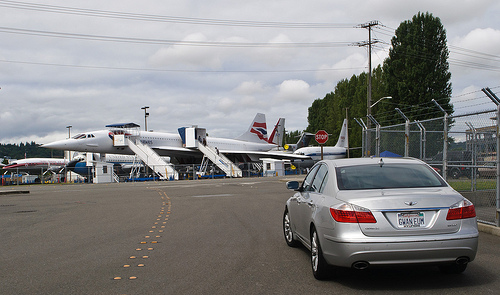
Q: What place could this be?
A: It is an airport.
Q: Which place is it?
A: It is an airport.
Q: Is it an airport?
A: Yes, it is an airport.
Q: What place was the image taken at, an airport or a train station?
A: It was taken at an airport.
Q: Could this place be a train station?
A: No, it is an airport.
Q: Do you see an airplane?
A: Yes, there is an airplane.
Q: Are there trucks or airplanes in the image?
A: Yes, there is an airplane.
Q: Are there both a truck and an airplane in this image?
A: No, there is an airplane but no trucks.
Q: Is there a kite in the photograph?
A: No, there are no kites.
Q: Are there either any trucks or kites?
A: No, there are no kites or trucks.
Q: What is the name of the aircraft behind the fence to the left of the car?
A: The aircraft is an airplane.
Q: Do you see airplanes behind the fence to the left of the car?
A: Yes, there is an airplane behind the fence.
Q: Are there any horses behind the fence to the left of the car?
A: No, there is an airplane behind the fence.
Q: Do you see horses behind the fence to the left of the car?
A: No, there is an airplane behind the fence.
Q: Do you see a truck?
A: No, there are no trucks.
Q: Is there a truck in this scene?
A: No, there are no trucks.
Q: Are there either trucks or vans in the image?
A: No, there are no trucks or vans.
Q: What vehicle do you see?
A: The vehicle is a car.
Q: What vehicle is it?
A: The vehicle is a car.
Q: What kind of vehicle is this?
A: This is a car.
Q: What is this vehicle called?
A: This is a car.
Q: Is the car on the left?
A: No, the car is on the right of the image.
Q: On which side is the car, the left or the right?
A: The car is on the right of the image.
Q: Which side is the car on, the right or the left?
A: The car is on the right of the image.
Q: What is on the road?
A: The car is on the road.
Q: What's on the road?
A: The car is on the road.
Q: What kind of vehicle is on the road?
A: The vehicle is a car.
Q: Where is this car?
A: The car is on the road.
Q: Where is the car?
A: The car is on the road.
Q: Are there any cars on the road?
A: Yes, there is a car on the road.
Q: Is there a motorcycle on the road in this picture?
A: No, there is a car on the road.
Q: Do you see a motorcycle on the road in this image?
A: No, there is a car on the road.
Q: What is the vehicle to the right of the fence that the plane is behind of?
A: The vehicle is a car.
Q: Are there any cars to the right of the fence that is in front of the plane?
A: Yes, there is a car to the right of the fence.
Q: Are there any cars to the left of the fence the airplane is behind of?
A: No, the car is to the right of the fence.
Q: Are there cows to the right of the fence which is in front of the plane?
A: No, there is a car to the right of the fence.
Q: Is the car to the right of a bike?
A: No, the car is to the right of the fence.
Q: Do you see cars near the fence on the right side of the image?
A: Yes, there is a car near the fence.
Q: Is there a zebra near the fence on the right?
A: No, there is a car near the fence.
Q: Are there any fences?
A: Yes, there is a fence.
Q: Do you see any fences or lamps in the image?
A: Yes, there is a fence.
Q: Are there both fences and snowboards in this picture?
A: No, there is a fence but no snowboards.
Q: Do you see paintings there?
A: No, there are no paintings.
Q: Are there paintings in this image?
A: No, there are no paintings.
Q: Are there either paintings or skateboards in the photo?
A: No, there are no paintings or skateboards.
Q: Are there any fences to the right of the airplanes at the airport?
A: Yes, there is a fence to the right of the planes.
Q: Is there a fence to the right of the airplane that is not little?
A: Yes, there is a fence to the right of the airplane.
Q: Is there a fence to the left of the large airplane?
A: No, the fence is to the right of the plane.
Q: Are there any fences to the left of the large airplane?
A: No, the fence is to the right of the plane.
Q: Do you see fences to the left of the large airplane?
A: No, the fence is to the right of the plane.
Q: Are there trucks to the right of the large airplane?
A: No, there is a fence to the right of the plane.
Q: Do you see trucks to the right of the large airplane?
A: No, there is a fence to the right of the plane.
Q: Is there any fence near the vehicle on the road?
A: Yes, there is a fence near the car.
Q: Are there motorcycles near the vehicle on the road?
A: No, there is a fence near the car.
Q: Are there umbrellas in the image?
A: No, there are no umbrellas.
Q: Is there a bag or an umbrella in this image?
A: No, there are no umbrellas or bags.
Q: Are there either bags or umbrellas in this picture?
A: No, there are no umbrellas or bags.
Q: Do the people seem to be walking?
A: Yes, the people are walking.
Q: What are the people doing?
A: The people are walking.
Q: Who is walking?
A: The people are walking.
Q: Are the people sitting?
A: No, the people are walking.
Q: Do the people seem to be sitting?
A: No, the people are walking.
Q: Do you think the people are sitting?
A: No, the people are walking.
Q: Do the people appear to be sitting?
A: No, the people are walking.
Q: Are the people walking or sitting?
A: The people are walking.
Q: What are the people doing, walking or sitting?
A: The people are walking.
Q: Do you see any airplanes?
A: Yes, there are airplanes.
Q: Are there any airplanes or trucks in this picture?
A: Yes, there are airplanes.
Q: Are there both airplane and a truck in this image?
A: No, there are airplanes but no trucks.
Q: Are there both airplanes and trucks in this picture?
A: No, there are airplanes but no trucks.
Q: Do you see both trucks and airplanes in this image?
A: No, there are airplanes but no trucks.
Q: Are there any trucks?
A: No, there are no trucks.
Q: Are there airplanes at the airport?
A: Yes, there are airplanes at the airport.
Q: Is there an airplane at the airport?
A: Yes, there are airplanes at the airport.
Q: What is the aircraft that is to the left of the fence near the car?
A: The aircraft is airplanes.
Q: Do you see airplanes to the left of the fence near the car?
A: Yes, there are airplanes to the left of the fence.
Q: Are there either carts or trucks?
A: No, there are no trucks or carts.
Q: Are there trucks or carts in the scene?
A: No, there are no trucks or carts.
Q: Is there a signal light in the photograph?
A: No, there are no traffic lights.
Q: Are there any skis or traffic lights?
A: No, there are no traffic lights or skis.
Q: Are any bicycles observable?
A: No, there are no bicycles.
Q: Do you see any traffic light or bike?
A: No, there are no bikes or traffic lights.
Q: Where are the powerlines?
A: The powerlines are in the sky.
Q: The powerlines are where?
A: The powerlines are in the sky.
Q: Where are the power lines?
A: The powerlines are in the sky.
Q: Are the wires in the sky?
A: Yes, the wires are in the sky.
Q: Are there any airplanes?
A: Yes, there is an airplane.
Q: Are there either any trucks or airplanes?
A: Yes, there is an airplane.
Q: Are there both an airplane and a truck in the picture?
A: No, there is an airplane but no trucks.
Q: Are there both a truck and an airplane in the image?
A: No, there is an airplane but no trucks.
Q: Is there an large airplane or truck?
A: Yes, there is a large airplane.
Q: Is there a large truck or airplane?
A: Yes, there is a large airplane.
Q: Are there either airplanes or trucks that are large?
A: Yes, the airplane is large.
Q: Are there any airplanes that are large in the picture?
A: Yes, there is a large airplane.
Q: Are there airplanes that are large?
A: Yes, there is an airplane that is large.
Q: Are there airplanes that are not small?
A: Yes, there is a large airplane.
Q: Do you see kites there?
A: No, there are no kites.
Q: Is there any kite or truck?
A: No, there are no kites or trucks.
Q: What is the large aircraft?
A: The aircraft is an airplane.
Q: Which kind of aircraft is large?
A: The aircraft is an airplane.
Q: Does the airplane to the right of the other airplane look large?
A: Yes, the airplane is large.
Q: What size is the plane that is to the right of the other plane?
A: The plane is large.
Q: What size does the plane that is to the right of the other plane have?
A: The plane has large size.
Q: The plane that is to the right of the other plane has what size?
A: The plane is large.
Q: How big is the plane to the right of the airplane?
A: The plane is large.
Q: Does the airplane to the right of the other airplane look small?
A: No, the plane is large.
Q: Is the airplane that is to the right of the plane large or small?
A: The plane is large.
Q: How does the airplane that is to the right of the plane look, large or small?
A: The plane is large.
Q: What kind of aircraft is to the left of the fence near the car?
A: The aircraft is an airplane.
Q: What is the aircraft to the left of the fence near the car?
A: The aircraft is an airplane.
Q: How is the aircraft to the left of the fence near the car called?
A: The aircraft is an airplane.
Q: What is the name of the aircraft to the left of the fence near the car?
A: The aircraft is an airplane.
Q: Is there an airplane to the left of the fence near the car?
A: Yes, there is an airplane to the left of the fence.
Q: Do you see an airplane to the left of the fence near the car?
A: Yes, there is an airplane to the left of the fence.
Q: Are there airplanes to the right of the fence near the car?
A: No, the airplane is to the left of the fence.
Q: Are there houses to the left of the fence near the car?
A: No, there is an airplane to the left of the fence.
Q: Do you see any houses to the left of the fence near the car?
A: No, there is an airplane to the left of the fence.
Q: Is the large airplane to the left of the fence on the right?
A: Yes, the airplane is to the left of the fence.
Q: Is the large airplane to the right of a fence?
A: No, the plane is to the left of a fence.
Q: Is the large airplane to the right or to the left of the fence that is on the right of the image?
A: The plane is to the left of the fence.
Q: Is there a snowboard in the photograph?
A: No, there are no snowboards.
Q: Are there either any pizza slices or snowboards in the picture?
A: No, there are no snowboards or pizza slices.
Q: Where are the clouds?
A: The clouds are in the sky.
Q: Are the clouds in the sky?
A: Yes, the clouds are in the sky.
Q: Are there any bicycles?
A: No, there are no bicycles.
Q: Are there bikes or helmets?
A: No, there are no bikes or helmets.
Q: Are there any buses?
A: No, there are no buses.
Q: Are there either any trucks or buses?
A: No, there are no buses or trucks.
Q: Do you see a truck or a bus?
A: No, there are no buses or trucks.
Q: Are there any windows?
A: Yes, there are windows.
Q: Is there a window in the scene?
A: Yes, there are windows.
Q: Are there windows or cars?
A: Yes, there are windows.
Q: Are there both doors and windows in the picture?
A: No, there are windows but no doors.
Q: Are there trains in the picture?
A: No, there are no trains.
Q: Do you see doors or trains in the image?
A: No, there are no trains or doors.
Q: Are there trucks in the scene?
A: No, there are no trucks.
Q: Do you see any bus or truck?
A: No, there are no trucks or buses.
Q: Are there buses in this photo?
A: No, there are no buses.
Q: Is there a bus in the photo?
A: No, there are no buses.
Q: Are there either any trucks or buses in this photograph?
A: No, there are no buses or trucks.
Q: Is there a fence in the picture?
A: Yes, there is a fence.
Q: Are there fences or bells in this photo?
A: Yes, there is a fence.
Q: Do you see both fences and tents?
A: No, there is a fence but no tents.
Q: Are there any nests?
A: No, there are no nests.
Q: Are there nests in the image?
A: No, there are no nests.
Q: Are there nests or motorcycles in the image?
A: No, there are no nests or motorcycles.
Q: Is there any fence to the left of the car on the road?
A: Yes, there is a fence to the left of the car.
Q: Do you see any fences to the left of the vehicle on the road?
A: Yes, there is a fence to the left of the car.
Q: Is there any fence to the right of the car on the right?
A: No, the fence is to the left of the car.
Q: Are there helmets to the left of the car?
A: No, there is a fence to the left of the car.